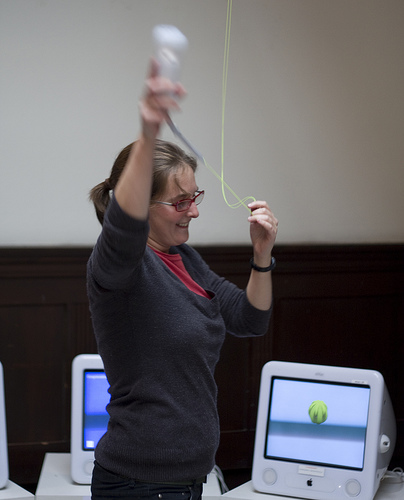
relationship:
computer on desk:
[1, 348, 398, 499] [4, 440, 403, 498]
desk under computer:
[4, 440, 403, 498] [1, 348, 398, 499]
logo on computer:
[301, 477, 319, 491] [1, 348, 398, 499]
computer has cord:
[1, 348, 398, 499] [210, 464, 402, 484]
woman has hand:
[84, 23, 302, 499] [129, 60, 282, 241]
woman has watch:
[84, 23, 302, 499] [251, 248, 279, 281]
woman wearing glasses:
[84, 23, 302, 499] [144, 190, 210, 211]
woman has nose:
[84, 23, 302, 499] [183, 202, 199, 222]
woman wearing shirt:
[84, 23, 302, 499] [75, 195, 242, 489]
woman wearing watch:
[84, 23, 302, 499] [251, 248, 279, 281]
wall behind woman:
[1, 1, 401, 484] [84, 23, 302, 499]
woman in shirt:
[84, 23, 302, 499] [75, 195, 242, 489]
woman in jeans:
[84, 23, 302, 499] [82, 453, 211, 499]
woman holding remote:
[84, 23, 302, 499] [146, 20, 190, 123]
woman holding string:
[84, 23, 302, 499] [219, 3, 282, 234]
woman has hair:
[84, 23, 302, 499] [84, 138, 186, 196]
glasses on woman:
[144, 190, 210, 211] [84, 23, 302, 499]